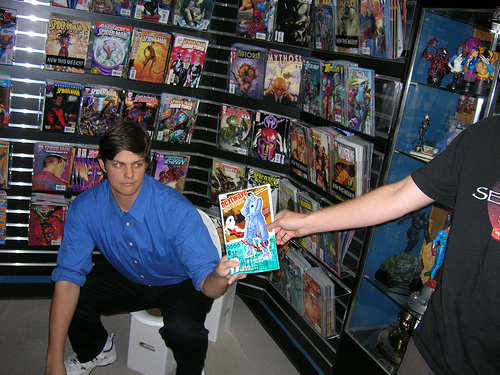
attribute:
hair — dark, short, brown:
[98, 117, 151, 162]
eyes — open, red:
[117, 164, 142, 170]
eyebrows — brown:
[110, 159, 143, 167]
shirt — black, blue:
[53, 180, 227, 300]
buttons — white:
[122, 222, 152, 285]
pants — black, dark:
[62, 259, 214, 374]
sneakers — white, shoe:
[61, 336, 119, 374]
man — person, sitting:
[26, 123, 240, 374]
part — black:
[411, 113, 488, 372]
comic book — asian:
[216, 183, 282, 276]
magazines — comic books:
[35, 0, 399, 343]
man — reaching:
[266, 90, 500, 368]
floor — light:
[1, 286, 327, 375]